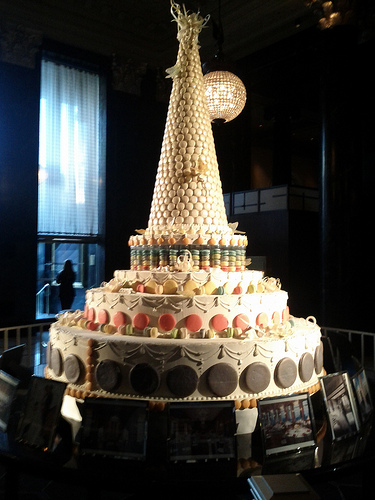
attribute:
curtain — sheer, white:
[30, 37, 107, 297]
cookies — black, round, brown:
[48, 358, 299, 388]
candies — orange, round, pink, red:
[96, 307, 265, 328]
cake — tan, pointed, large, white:
[30, 2, 332, 443]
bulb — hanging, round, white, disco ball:
[199, 67, 249, 126]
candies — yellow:
[108, 269, 283, 297]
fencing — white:
[2, 309, 374, 392]